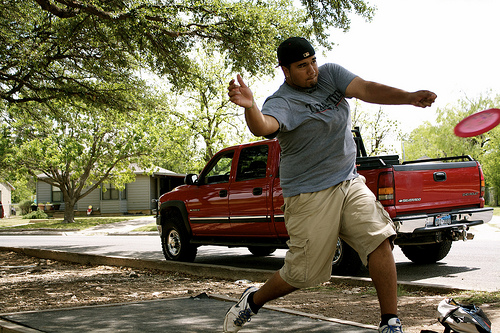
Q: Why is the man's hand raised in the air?
A: Throwing frisbee.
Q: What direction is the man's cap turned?
A: Backward.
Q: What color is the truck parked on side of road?
A: Red.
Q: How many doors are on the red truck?
A: Two.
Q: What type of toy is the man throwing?
A: Frisbee.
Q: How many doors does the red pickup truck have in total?
A: Four doors.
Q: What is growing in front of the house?
A: A tree.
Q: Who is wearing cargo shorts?
A: The man.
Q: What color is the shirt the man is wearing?
A: Gray.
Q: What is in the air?
A: Frisbee.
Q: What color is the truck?
A: Red.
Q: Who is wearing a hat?
A: The man.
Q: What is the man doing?
A: Playing frisbee.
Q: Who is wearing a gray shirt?
A: A man.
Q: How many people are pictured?
A: One.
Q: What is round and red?
A: The frisbee.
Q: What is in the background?
A: A house.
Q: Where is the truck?
A: On the road.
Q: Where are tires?
A: Under the truck.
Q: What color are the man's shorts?
A: Khaki.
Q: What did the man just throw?
A: Frisbee.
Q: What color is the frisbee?
A: Red.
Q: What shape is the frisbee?
A: Circle.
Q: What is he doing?
A: Playing frisbee.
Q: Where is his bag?
A: On the floor.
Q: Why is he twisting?
A: To steer the frisbee.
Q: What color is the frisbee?
A: It is red.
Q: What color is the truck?
A: The truck is red.